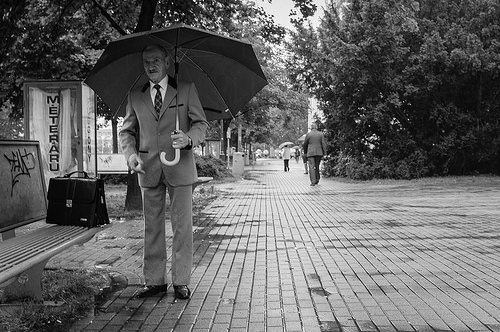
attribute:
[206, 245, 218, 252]
brick — wet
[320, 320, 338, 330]
brick — wet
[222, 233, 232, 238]
brick — wet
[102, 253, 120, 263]
brick — wet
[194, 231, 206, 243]
brick — wet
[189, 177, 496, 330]
brick — wet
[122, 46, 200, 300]
person — standing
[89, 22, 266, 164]
umbrella — large, open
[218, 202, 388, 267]
sidewalk — wet, brick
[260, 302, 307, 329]
brick — wet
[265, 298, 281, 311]
brick — wet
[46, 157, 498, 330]
sidewalk — brick, wet